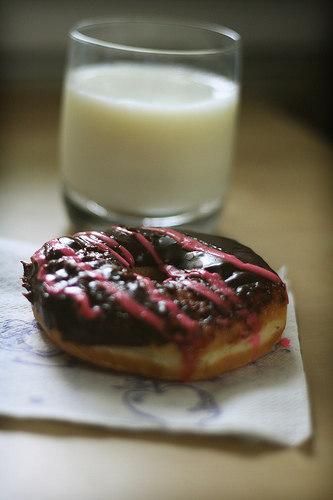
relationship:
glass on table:
[37, 19, 257, 238] [242, 121, 311, 206]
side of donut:
[206, 278, 282, 330] [14, 209, 265, 411]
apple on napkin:
[136, 378, 223, 434] [14, 209, 265, 411]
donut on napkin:
[14, 209, 265, 411] [233, 348, 300, 439]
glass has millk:
[37, 19, 257, 238] [78, 78, 202, 150]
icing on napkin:
[165, 243, 216, 265] [233, 348, 300, 439]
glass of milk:
[37, 19, 257, 238] [78, 78, 202, 150]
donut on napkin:
[19, 222, 290, 383] [233, 348, 300, 439]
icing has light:
[165, 243, 216, 265] [202, 245, 224, 273]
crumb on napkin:
[207, 378, 254, 401] [233, 348, 300, 439]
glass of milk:
[37, 19, 257, 238] [187, 99, 213, 121]